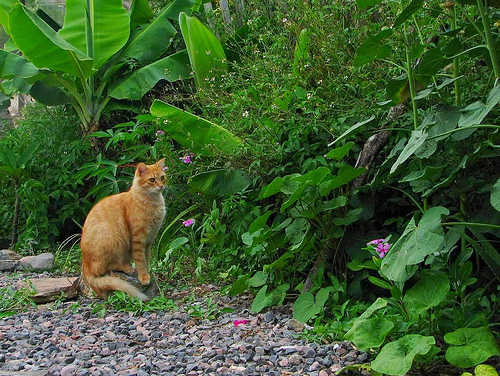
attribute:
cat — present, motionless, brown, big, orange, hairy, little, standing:
[79, 155, 168, 303]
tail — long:
[80, 269, 150, 303]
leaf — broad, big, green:
[149, 99, 245, 163]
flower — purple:
[375, 241, 391, 257]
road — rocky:
[2, 293, 380, 376]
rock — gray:
[14, 275, 81, 306]